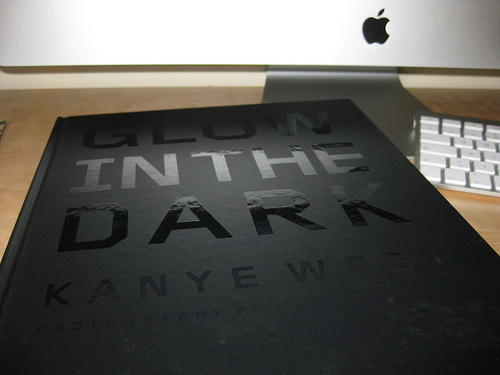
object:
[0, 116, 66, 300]
crease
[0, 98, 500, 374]
cover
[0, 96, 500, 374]
album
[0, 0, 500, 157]
computer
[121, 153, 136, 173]
light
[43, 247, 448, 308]
author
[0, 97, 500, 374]
book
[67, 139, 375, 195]
text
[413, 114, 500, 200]
keyboard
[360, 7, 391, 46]
logo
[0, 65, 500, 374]
desk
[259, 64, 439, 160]
monitor stand